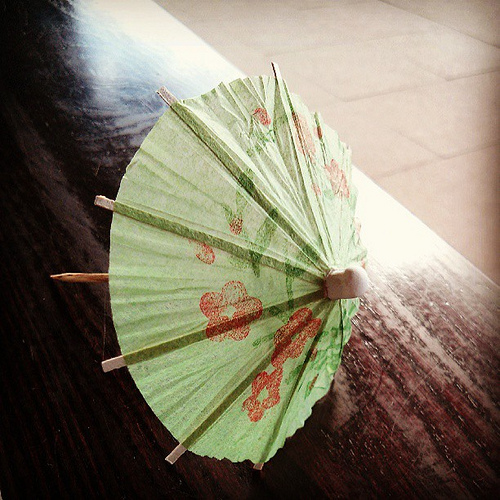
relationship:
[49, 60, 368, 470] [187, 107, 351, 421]
umbrella has flowers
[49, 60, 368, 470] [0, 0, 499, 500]
umbrella on table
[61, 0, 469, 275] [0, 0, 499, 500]
light on table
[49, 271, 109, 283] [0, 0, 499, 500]
stake on table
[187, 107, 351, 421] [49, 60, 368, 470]
flowers on umbrella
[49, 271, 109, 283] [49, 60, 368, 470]
stake on umbrella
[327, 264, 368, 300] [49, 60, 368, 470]
knob on umbrella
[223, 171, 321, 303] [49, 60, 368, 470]
leaf on umbrella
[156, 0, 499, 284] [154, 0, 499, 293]
tile on floor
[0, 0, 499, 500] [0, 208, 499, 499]
table has lines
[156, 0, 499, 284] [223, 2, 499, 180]
tile has lines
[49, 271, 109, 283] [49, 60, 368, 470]
stake has umbrella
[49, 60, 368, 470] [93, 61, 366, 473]
umbrella has ribs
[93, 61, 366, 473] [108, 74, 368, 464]
ribs beyond paper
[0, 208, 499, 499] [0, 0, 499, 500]
lines on table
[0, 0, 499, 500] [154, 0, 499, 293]
table next to floor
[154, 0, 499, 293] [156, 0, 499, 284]
floor has tile